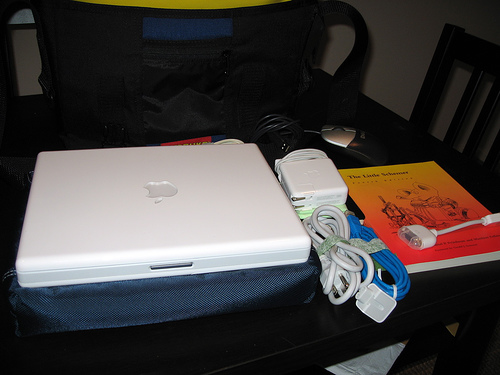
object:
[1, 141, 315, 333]
blue bag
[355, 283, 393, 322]
plug-in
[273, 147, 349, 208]
charger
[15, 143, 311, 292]
computer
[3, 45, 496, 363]
desk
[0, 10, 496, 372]
room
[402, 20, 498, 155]
chair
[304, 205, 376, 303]
cables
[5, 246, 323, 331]
case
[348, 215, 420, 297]
cord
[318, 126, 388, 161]
mouse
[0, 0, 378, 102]
chair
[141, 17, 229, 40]
stripe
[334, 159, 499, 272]
book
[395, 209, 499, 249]
cord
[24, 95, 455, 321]
desktop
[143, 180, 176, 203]
logo